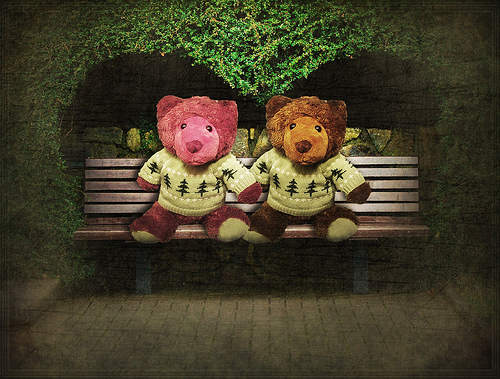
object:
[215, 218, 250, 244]
foot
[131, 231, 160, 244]
foot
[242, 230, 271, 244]
foot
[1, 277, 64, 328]
steps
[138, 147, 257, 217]
sweater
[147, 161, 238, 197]
tree design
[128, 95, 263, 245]
teddy bear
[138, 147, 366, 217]
shirt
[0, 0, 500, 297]
bush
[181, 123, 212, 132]
eyes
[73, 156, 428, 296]
bench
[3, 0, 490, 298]
wall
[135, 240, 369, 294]
leg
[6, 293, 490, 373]
brick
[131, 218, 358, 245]
feet